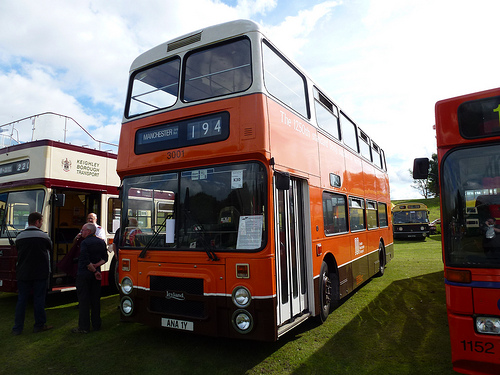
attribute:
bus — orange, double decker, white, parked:
[116, 19, 394, 341]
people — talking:
[12, 210, 109, 335]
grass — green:
[275, 231, 444, 374]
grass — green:
[2, 298, 283, 373]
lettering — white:
[279, 111, 363, 165]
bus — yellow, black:
[391, 202, 432, 241]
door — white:
[273, 169, 314, 328]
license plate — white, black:
[161, 316, 194, 331]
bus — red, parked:
[413, 86, 499, 374]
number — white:
[186, 117, 222, 140]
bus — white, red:
[0, 111, 121, 299]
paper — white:
[235, 213, 264, 249]